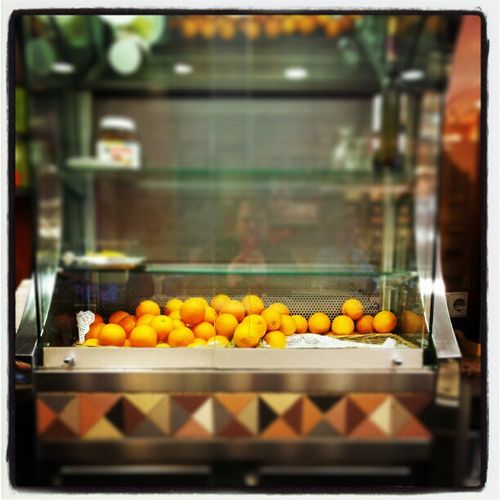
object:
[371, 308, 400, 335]
oranges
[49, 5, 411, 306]
rack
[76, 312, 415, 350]
paper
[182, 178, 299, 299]
reflection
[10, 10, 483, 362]
glass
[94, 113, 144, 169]
bottle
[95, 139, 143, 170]
label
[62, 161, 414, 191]
top shelf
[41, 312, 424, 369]
tray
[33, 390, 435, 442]
design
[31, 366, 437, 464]
bottom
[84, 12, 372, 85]
reflection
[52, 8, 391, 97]
glass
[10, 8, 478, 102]
top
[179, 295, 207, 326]
orange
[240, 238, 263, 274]
mobile phone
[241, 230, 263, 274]
cellphone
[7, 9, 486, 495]
picture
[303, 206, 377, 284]
person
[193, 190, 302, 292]
individual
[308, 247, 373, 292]
shirt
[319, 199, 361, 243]
hair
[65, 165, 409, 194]
shelf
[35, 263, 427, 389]
shelf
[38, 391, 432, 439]
strip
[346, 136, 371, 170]
bottle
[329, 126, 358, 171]
bottle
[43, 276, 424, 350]
bin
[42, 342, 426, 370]
piece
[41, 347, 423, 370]
item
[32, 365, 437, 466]
front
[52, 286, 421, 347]
enclosure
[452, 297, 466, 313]
knob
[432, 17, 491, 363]
wall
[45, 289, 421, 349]
basket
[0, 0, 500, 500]
cabinet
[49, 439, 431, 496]
door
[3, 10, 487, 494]
case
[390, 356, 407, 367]
knob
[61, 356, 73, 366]
knob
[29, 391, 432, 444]
shapes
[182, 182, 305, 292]
man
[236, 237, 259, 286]
cup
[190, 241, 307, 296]
clothing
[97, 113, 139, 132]
lid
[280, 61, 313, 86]
light